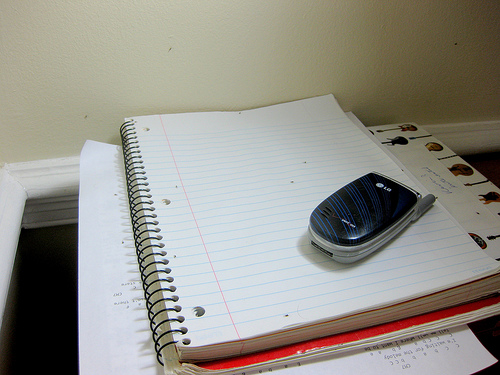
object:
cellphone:
[314, 166, 416, 253]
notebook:
[114, 110, 472, 341]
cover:
[320, 195, 388, 216]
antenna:
[421, 188, 437, 214]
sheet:
[78, 151, 146, 363]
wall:
[55, 16, 494, 106]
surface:
[23, 204, 76, 364]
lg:
[383, 181, 404, 194]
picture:
[34, 23, 496, 296]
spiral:
[113, 126, 157, 283]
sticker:
[400, 116, 493, 260]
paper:
[59, 148, 154, 375]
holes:
[147, 118, 169, 226]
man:
[468, 229, 485, 259]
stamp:
[467, 215, 500, 275]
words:
[119, 232, 145, 310]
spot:
[83, 346, 99, 375]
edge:
[314, 237, 343, 257]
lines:
[344, 191, 380, 220]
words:
[333, 217, 359, 236]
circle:
[377, 178, 387, 189]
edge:
[407, 120, 500, 156]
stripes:
[334, 202, 390, 233]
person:
[387, 129, 416, 149]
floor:
[464, 150, 499, 175]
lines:
[206, 149, 378, 181]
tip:
[420, 187, 443, 205]